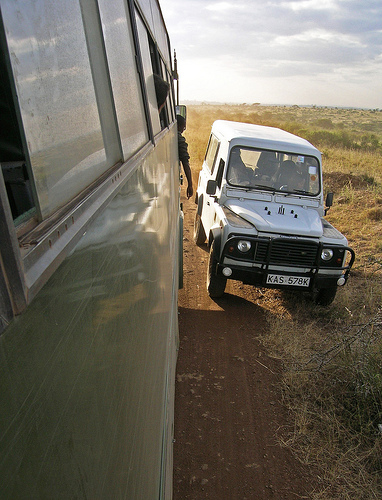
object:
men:
[154, 78, 170, 117]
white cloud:
[153, 0, 382, 99]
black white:
[266, 274, 310, 288]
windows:
[0, 0, 154, 236]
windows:
[215, 158, 225, 191]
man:
[228, 148, 251, 186]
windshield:
[226, 143, 320, 196]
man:
[172, 104, 194, 200]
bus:
[0, 0, 187, 497]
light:
[237, 240, 252, 253]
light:
[321, 248, 334, 262]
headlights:
[320, 248, 333, 262]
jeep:
[193, 117, 356, 307]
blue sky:
[162, 0, 378, 106]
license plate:
[266, 274, 310, 288]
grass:
[266, 320, 380, 498]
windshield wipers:
[255, 184, 277, 190]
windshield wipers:
[293, 186, 315, 194]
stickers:
[308, 166, 317, 174]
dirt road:
[178, 142, 306, 499]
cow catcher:
[221, 235, 355, 285]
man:
[278, 159, 307, 194]